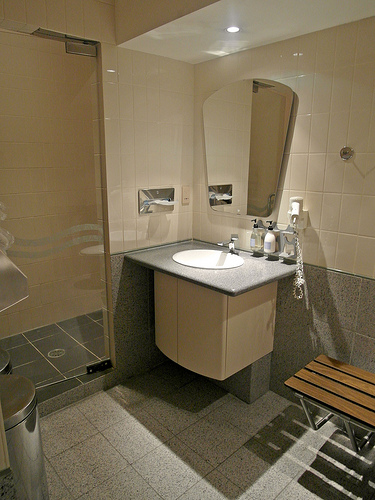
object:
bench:
[283, 353, 374, 453]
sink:
[172, 249, 245, 271]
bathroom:
[1, 0, 374, 499]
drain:
[47, 346, 67, 360]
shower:
[0, 29, 110, 389]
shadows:
[103, 358, 340, 499]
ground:
[40, 361, 374, 499]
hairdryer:
[286, 196, 311, 310]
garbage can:
[0, 373, 44, 498]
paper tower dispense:
[138, 188, 177, 215]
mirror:
[201, 78, 295, 218]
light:
[227, 25, 240, 35]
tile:
[39, 360, 373, 498]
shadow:
[243, 405, 374, 498]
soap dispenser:
[249, 217, 261, 251]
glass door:
[0, 32, 110, 389]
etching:
[1, 203, 105, 259]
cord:
[291, 224, 305, 299]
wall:
[193, 15, 373, 444]